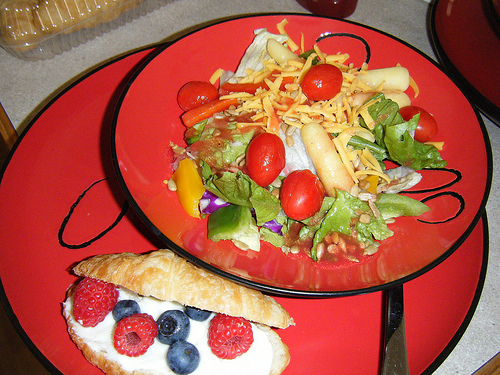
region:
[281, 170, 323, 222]
red tomato in salad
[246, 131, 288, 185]
red tomato in salad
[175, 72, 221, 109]
red tomato in salad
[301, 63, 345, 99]
red tomato in salad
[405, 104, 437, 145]
red tomato in salad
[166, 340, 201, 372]
a blueberry on pastry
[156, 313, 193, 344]
a blueberry on pastry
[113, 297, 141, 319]
a blueberry on pastry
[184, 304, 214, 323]
a blueberry on pastry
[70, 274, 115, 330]
a raspberry on pastry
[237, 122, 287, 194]
grape tomato in the salad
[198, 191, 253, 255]
piece of green pepper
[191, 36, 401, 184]
shredded cheese on top of the salad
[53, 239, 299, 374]
pastry filled with cream cheese and berries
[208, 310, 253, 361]
raspberry in the pastry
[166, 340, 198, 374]
blueberry in the pastry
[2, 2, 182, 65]
plastic containers of pastries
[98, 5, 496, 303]
red and black salad bowl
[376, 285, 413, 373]
handle of a utensil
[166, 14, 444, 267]
salad that includes lettuce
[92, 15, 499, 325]
a red plate with food on it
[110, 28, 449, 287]
a red plate with salad on it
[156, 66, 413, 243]
a red plate with grape tomatoes on it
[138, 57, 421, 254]
a red plate with lettuce on it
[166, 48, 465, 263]
a red plate with cheese on it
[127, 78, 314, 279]
a red plate with yellow peppers on it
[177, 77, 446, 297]
a rd plate with salad dressing on it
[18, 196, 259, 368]
a red plate with raspberries on it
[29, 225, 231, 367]
a red plate with blueberries on it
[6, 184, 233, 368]
a red plate with a pastry on it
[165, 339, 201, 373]
Blueberry on the food.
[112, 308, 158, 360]
raspberry on the food.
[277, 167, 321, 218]
tomato in the dish.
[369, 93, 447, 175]
Lettuce in the dish.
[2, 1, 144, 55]
Plastic container in the background.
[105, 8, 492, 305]
Red plate with salad in it.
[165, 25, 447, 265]
Salad in the dish.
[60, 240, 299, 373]
Puff pastry on the plate.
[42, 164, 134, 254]
Black design on the plate.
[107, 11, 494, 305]
Black rim on the plate.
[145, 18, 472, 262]
Food on a plate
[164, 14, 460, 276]
Food on a red plate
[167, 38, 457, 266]
Salad on a plate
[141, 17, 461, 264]
Salad on a red plate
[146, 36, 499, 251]
Red plate with food on it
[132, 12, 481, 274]
Plate with salad on it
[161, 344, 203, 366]
a blueberry on a piece of bread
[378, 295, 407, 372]
Eating utensil on a plate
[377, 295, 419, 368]
Eating utensil on a red plate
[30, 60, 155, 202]
Two plates on top of eachother